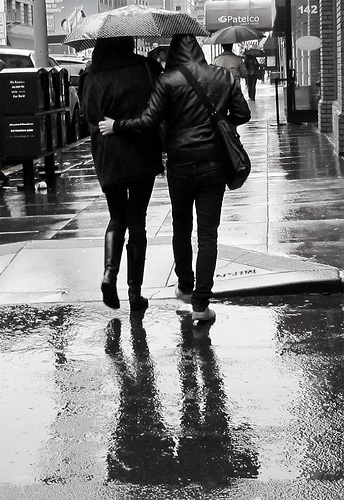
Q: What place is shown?
A: It is a sidewalk.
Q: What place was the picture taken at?
A: It was taken at the sidewalk.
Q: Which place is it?
A: It is a sidewalk.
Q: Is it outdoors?
A: Yes, it is outdoors.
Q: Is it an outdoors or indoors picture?
A: It is outdoors.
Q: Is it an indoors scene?
A: No, it is outdoors.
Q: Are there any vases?
A: No, there are no vases.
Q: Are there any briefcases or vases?
A: No, there are no vases or briefcases.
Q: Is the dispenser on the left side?
A: Yes, the dispenser is on the left of the image.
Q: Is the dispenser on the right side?
A: No, the dispenser is on the left of the image.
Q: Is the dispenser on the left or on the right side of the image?
A: The dispenser is on the left of the image.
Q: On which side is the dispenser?
A: The dispenser is on the left of the image.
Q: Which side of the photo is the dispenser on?
A: The dispenser is on the left of the image.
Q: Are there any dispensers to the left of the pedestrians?
A: Yes, there is a dispenser to the left of the pedestrians.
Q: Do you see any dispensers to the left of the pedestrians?
A: Yes, there is a dispenser to the left of the pedestrians.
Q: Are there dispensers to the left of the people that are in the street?
A: Yes, there is a dispenser to the left of the pedestrians.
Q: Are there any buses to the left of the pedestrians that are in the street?
A: No, there is a dispenser to the left of the pedestrians.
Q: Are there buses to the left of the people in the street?
A: No, there is a dispenser to the left of the pedestrians.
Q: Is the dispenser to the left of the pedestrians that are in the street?
A: Yes, the dispenser is to the left of the pedestrians.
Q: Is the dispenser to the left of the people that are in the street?
A: Yes, the dispenser is to the left of the pedestrians.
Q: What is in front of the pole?
A: The dispenser is in front of the pole.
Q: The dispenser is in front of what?
A: The dispenser is in front of the pole.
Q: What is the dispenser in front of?
A: The dispenser is in front of the pole.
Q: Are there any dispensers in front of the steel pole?
A: Yes, there is a dispenser in front of the pole.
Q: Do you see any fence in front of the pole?
A: No, there is a dispenser in front of the pole.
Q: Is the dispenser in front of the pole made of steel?
A: Yes, the dispenser is in front of the pole.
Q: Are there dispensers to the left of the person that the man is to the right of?
A: Yes, there is a dispenser to the left of the person.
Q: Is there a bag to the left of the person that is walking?
A: No, there is a dispenser to the left of the person.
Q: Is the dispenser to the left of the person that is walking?
A: Yes, the dispenser is to the left of the person.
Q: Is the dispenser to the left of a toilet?
A: No, the dispenser is to the left of the person.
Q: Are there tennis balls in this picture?
A: No, there are no tennis balls.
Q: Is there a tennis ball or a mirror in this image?
A: No, there are no tennis balls or mirrors.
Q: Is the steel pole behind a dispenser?
A: Yes, the pole is behind a dispenser.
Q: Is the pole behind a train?
A: No, the pole is behind a dispenser.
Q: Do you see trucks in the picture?
A: No, there are no trucks.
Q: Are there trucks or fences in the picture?
A: No, there are no trucks or fences.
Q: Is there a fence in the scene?
A: No, there are no fences.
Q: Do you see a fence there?
A: No, there are no fences.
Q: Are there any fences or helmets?
A: No, there are no fences or helmets.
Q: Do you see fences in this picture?
A: No, there are no fences.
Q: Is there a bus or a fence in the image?
A: No, there are no fences or buses.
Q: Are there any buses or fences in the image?
A: No, there are no fences or buses.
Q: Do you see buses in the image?
A: No, there are no buses.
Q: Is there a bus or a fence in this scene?
A: No, there are no buses or fences.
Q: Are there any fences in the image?
A: No, there are no fences.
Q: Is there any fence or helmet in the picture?
A: No, there are no fences or helmets.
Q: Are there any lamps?
A: No, there are no lamps.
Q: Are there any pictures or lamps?
A: No, there are no lamps or pictures.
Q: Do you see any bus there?
A: No, there are no buses.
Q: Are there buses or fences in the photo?
A: No, there are no buses or fences.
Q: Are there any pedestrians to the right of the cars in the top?
A: Yes, there are pedestrians to the right of the cars.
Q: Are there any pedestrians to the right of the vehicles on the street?
A: Yes, there are pedestrians to the right of the cars.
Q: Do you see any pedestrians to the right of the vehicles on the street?
A: Yes, there are pedestrians to the right of the cars.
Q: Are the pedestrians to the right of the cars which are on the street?
A: Yes, the pedestrians are to the right of the cars.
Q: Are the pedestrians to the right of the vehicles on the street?
A: Yes, the pedestrians are to the right of the cars.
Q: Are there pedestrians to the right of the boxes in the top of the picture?
A: Yes, there are pedestrians to the right of the boxes.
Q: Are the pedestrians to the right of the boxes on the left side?
A: Yes, the pedestrians are to the right of the boxes.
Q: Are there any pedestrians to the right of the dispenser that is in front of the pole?
A: Yes, there are pedestrians to the right of the dispenser.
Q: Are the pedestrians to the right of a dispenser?
A: Yes, the pedestrians are to the right of a dispenser.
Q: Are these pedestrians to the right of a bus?
A: No, the pedestrians are to the right of a dispenser.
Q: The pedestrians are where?
A: The pedestrians are in the street.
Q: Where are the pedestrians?
A: The pedestrians are in the street.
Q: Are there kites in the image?
A: No, there are no kites.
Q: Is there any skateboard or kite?
A: No, there are no kites or skateboards.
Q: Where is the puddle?
A: The puddle is on the street.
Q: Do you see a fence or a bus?
A: No, there are no fences or buses.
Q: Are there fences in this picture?
A: No, there are no fences.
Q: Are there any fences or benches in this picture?
A: No, there are no fences or benches.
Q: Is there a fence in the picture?
A: No, there are no fences.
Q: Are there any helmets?
A: No, there are no helmets.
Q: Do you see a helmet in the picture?
A: No, there are no helmets.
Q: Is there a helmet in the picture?
A: No, there are no helmets.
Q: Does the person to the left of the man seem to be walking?
A: Yes, the person is walking.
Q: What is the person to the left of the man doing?
A: The person is walking.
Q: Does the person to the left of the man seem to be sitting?
A: No, the person is walking.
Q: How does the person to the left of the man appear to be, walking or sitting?
A: The person is walking.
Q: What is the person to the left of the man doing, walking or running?
A: The person is walking.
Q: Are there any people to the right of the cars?
A: Yes, there is a person to the right of the cars.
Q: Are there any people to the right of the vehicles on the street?
A: Yes, there is a person to the right of the cars.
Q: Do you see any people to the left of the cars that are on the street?
A: No, the person is to the right of the cars.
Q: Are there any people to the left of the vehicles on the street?
A: No, the person is to the right of the cars.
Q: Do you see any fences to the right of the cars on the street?
A: No, there is a person to the right of the cars.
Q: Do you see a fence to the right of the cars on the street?
A: No, there is a person to the right of the cars.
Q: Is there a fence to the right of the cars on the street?
A: No, there is a person to the right of the cars.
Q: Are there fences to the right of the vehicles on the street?
A: No, there is a person to the right of the cars.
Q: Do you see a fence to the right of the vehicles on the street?
A: No, there is a person to the right of the cars.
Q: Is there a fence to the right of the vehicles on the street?
A: No, there is a person to the right of the cars.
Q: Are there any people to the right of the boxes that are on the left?
A: Yes, there is a person to the right of the boxes.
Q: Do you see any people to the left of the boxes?
A: No, the person is to the right of the boxes.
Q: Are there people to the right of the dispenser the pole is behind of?
A: Yes, there is a person to the right of the dispenser.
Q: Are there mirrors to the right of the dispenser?
A: No, there is a person to the right of the dispenser.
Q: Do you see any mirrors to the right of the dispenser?
A: No, there is a person to the right of the dispenser.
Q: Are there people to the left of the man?
A: Yes, there is a person to the left of the man.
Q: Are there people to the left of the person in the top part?
A: Yes, there is a person to the left of the man.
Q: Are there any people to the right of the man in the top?
A: No, the person is to the left of the man.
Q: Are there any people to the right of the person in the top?
A: No, the person is to the left of the man.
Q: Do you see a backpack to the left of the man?
A: No, there is a person to the left of the man.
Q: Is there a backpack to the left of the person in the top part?
A: No, there is a person to the left of the man.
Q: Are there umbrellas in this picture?
A: Yes, there is an umbrella.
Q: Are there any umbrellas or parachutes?
A: Yes, there is an umbrella.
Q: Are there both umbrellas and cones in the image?
A: No, there is an umbrella but no cones.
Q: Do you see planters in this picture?
A: No, there are no planters.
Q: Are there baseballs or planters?
A: No, there are no planters or baseballs.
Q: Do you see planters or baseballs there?
A: No, there are no planters or baseballs.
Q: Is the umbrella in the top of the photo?
A: Yes, the umbrella is in the top of the image.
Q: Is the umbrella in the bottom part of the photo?
A: No, the umbrella is in the top of the image.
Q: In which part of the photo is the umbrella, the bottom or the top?
A: The umbrella is in the top of the image.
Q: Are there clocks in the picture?
A: No, there are no clocks.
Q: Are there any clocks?
A: No, there are no clocks.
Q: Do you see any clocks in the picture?
A: No, there are no clocks.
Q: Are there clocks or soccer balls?
A: No, there are no clocks or soccer balls.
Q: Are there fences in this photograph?
A: No, there are no fences.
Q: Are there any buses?
A: No, there are no buses.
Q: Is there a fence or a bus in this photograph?
A: No, there are no buses or fences.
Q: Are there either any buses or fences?
A: No, there are no buses or fences.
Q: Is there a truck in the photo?
A: No, there are no trucks.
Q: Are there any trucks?
A: No, there are no trucks.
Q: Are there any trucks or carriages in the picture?
A: No, there are no trucks or carriages.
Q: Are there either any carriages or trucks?
A: No, there are no trucks or carriages.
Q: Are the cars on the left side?
A: Yes, the cars are on the left of the image.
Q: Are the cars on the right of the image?
A: No, the cars are on the left of the image.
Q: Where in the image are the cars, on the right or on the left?
A: The cars are on the left of the image.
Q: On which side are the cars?
A: The cars are on the left of the image.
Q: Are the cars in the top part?
A: Yes, the cars are in the top of the image.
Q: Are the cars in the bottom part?
A: No, the cars are in the top of the image.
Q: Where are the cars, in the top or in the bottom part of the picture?
A: The cars are in the top of the image.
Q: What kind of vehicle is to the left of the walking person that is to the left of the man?
A: The vehicles are cars.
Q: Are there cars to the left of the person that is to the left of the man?
A: Yes, there are cars to the left of the person.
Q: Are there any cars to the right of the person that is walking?
A: No, the cars are to the left of the person.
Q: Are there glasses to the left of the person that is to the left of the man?
A: No, there are cars to the left of the person.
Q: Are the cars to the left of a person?
A: Yes, the cars are to the left of a person.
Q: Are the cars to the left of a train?
A: No, the cars are to the left of a person.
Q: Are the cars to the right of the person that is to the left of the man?
A: No, the cars are to the left of the person.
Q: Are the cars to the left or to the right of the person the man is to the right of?
A: The cars are to the left of the person.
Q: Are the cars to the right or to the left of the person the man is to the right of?
A: The cars are to the left of the person.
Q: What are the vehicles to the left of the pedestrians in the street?
A: The vehicles are cars.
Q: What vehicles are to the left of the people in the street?
A: The vehicles are cars.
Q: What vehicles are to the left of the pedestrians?
A: The vehicles are cars.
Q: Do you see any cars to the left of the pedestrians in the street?
A: Yes, there are cars to the left of the pedestrians.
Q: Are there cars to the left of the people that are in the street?
A: Yes, there are cars to the left of the pedestrians.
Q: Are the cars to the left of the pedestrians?
A: Yes, the cars are to the left of the pedestrians.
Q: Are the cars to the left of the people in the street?
A: Yes, the cars are to the left of the pedestrians.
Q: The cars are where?
A: The cars are on the street.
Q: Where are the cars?
A: The cars are on the street.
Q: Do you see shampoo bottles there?
A: No, there are no shampoo bottles.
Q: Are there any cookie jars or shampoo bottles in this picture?
A: No, there are no shampoo bottles or cookie jars.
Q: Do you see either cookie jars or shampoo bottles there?
A: No, there are no shampoo bottles or cookie jars.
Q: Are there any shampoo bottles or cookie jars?
A: No, there are no shampoo bottles or cookie jars.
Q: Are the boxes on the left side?
A: Yes, the boxes are on the left of the image.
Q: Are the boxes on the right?
A: No, the boxes are on the left of the image.